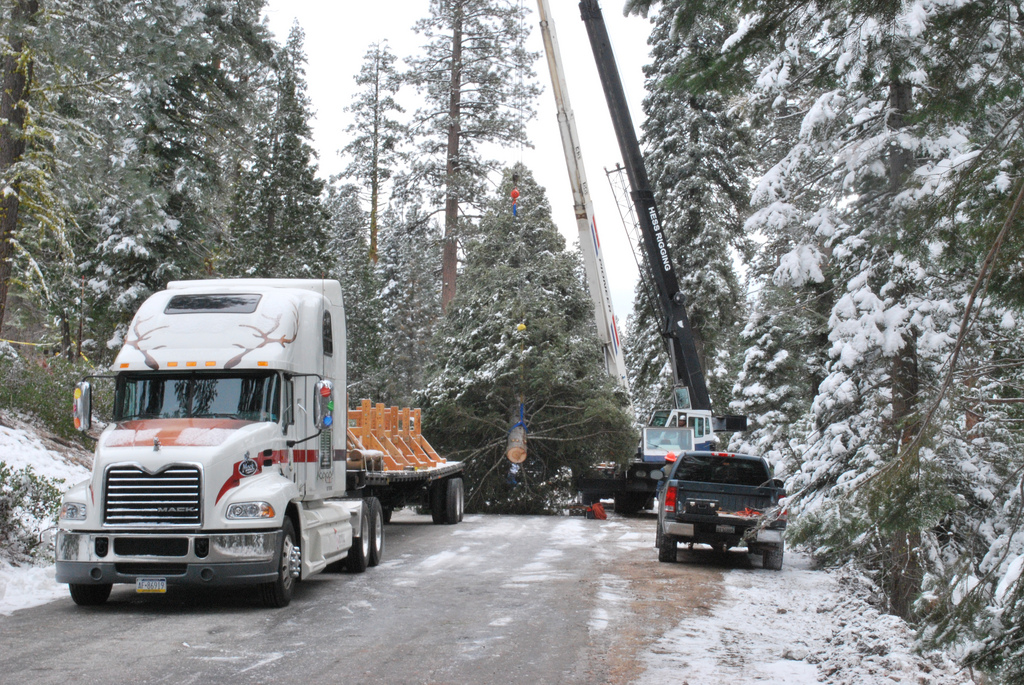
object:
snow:
[636, 569, 1024, 685]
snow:
[0, 414, 95, 612]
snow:
[550, 508, 649, 553]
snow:
[414, 547, 460, 572]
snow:
[194, 639, 295, 685]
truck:
[54, 275, 467, 609]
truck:
[655, 450, 786, 567]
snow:
[659, 0, 1024, 685]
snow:
[384, 161, 633, 517]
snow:
[0, 0, 187, 357]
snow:
[250, 0, 463, 324]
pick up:
[655, 450, 789, 571]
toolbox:
[684, 497, 719, 514]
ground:
[0, 470, 1022, 683]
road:
[0, 483, 941, 685]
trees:
[0, 0, 1024, 685]